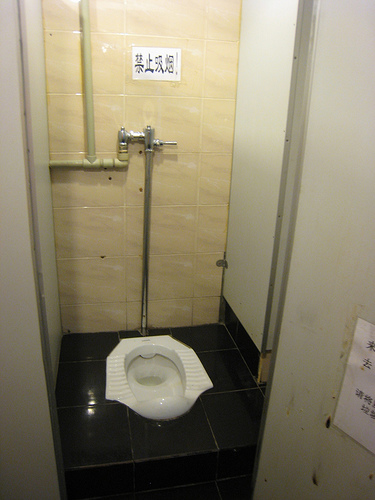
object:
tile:
[200, 35, 241, 101]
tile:
[195, 200, 231, 256]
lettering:
[145, 52, 155, 73]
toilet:
[103, 334, 215, 421]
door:
[250, 1, 375, 500]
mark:
[286, 409, 290, 415]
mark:
[325, 415, 331, 429]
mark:
[309, 472, 319, 488]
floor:
[56, 322, 265, 498]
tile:
[57, 401, 135, 465]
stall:
[117, 126, 179, 338]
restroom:
[0, 2, 373, 500]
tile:
[56, 257, 125, 305]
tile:
[150, 206, 198, 253]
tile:
[197, 155, 232, 205]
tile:
[94, 92, 124, 155]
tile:
[199, 95, 235, 156]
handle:
[153, 139, 179, 148]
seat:
[103, 334, 211, 425]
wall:
[219, 0, 302, 382]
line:
[197, 395, 222, 453]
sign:
[330, 315, 375, 456]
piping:
[140, 152, 155, 335]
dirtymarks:
[310, 470, 320, 490]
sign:
[132, 44, 181, 82]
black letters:
[134, 53, 145, 73]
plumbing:
[46, 0, 179, 333]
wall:
[42, 0, 241, 334]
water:
[138, 375, 162, 387]